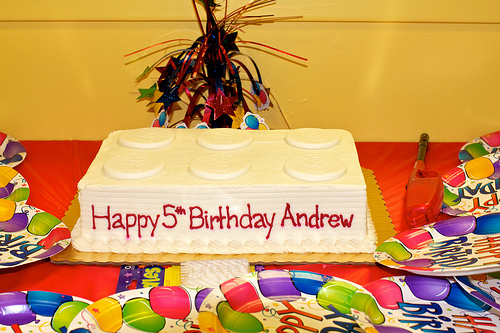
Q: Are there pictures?
A: No, there are no pictures.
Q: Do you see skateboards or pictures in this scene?
A: No, there are no pictures or skateboards.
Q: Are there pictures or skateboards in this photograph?
A: No, there are no pictures or skateboards.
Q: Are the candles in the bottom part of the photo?
A: Yes, the candles are in the bottom of the image.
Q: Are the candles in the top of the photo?
A: No, the candles are in the bottom of the image.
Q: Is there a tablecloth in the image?
A: Yes, there is a tablecloth.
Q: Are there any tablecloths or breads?
A: Yes, there is a tablecloth.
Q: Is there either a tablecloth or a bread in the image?
A: Yes, there is a tablecloth.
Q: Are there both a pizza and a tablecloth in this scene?
A: No, there is a tablecloth but no pizzas.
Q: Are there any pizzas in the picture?
A: No, there are no pizzas.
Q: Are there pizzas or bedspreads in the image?
A: No, there are no pizzas or bedspreads.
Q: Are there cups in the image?
A: No, there are no cups.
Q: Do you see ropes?
A: No, there are no ropes.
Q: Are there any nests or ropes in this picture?
A: No, there are no ropes or nests.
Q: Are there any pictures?
A: No, there are no pictures.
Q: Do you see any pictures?
A: No, there are no pictures.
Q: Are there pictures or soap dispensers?
A: No, there are no pictures or soap dispensers.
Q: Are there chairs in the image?
A: No, there are no chairs.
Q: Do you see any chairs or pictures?
A: No, there are no chairs or pictures.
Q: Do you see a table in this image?
A: Yes, there is a table.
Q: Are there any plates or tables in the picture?
A: Yes, there is a table.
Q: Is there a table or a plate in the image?
A: Yes, there is a table.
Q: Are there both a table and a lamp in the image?
A: No, there is a table but no lamps.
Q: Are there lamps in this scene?
A: No, there are no lamps.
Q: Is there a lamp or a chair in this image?
A: No, there are no lamps or chairs.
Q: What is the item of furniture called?
A: The piece of furniture is a table.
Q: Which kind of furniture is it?
A: The piece of furniture is a table.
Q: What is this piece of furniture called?
A: That is a table.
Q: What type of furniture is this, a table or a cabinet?
A: That is a table.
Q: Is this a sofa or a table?
A: This is a table.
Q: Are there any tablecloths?
A: Yes, there is a tablecloth.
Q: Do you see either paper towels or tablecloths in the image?
A: Yes, there is a tablecloth.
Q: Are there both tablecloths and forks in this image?
A: No, there is a tablecloth but no forks.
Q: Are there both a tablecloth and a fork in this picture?
A: No, there is a tablecloth but no forks.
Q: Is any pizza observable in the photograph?
A: No, there are no pizzas.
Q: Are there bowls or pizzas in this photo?
A: No, there are no pizzas or bowls.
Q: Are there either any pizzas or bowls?
A: No, there are no pizzas or bowls.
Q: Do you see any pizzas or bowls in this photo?
A: No, there are no pizzas or bowls.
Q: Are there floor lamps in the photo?
A: No, there are no floor lamps.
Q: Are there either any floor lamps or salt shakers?
A: No, there are no floor lamps or salt shakers.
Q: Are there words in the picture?
A: Yes, there are words.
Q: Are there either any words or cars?
A: Yes, there are words.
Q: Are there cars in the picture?
A: No, there are no cars.